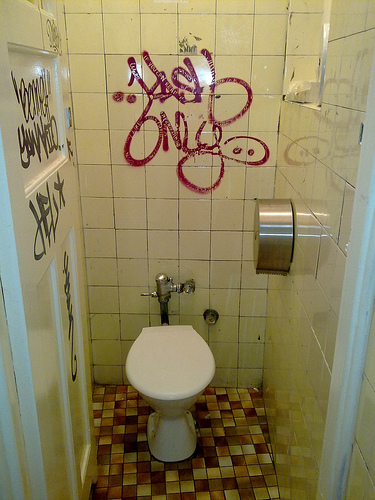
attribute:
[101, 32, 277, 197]
graffiti — red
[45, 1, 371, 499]
tiles — short, white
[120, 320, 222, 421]
toilet bowl — large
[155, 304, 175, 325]
pipe — metal, silver, stainless steel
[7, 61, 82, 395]
writing — black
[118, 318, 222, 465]
toilet — white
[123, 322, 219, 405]
lid — down, white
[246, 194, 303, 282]
toilet paper holder — metal, silver, shiny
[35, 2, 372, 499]
bathroom — white, dirty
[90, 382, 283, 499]
tile — multi-colored, light brown, brown, square, small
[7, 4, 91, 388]
graffiti — black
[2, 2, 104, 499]
door — open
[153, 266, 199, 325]
plumbing — stainless steel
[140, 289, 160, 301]
handle — metal, horizontal